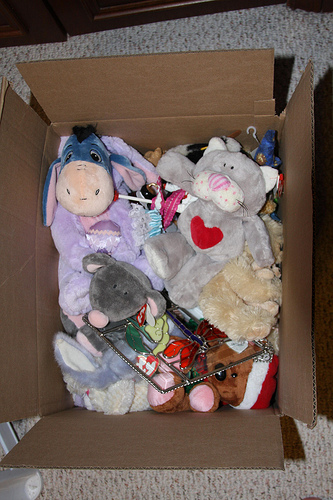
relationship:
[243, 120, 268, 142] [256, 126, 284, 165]
hook on toy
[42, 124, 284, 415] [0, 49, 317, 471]
animal inside box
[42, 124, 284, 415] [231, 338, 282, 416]
animal wearing hat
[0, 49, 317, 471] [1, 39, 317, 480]
box has edge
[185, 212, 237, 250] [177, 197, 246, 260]
heart on belly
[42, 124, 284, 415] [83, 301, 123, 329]
animal with nose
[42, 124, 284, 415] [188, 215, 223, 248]
animal with heart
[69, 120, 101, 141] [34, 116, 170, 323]
hair on eyore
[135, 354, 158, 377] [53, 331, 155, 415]
label on bear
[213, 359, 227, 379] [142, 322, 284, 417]
nose on bear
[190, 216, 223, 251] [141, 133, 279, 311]
heart on animal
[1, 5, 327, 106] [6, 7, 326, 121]
carpet on floor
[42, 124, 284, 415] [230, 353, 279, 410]
animal wearing hat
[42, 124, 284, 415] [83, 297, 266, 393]
animal in frame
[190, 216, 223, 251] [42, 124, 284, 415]
heart on animal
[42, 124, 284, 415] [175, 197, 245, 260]
animal has belly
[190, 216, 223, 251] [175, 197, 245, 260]
heart on belly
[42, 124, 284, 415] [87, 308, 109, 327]
animal has nose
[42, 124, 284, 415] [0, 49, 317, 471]
animal in box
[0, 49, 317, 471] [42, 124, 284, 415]
box full of animal